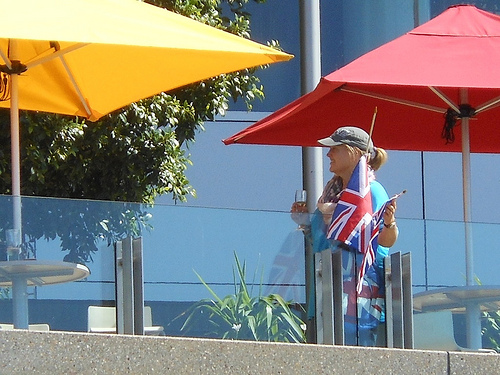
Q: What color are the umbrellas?
A: Yellow and red.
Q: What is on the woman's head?
A: Hat.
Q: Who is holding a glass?
A: The woman.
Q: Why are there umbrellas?
A: Shade.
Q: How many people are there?
A: One.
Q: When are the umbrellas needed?
A: Daytime.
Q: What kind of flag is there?
A: British.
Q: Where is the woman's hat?
A: On her head.